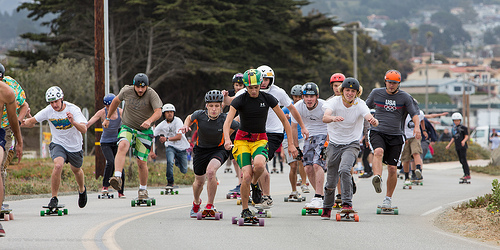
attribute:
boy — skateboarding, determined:
[235, 75, 265, 222]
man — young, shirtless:
[330, 82, 365, 207]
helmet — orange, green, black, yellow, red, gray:
[384, 69, 402, 82]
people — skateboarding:
[54, 75, 398, 206]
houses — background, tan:
[404, 50, 470, 100]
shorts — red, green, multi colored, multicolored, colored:
[109, 125, 153, 152]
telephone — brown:
[462, 101, 470, 113]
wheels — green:
[198, 212, 222, 222]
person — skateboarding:
[112, 70, 152, 209]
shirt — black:
[332, 105, 353, 140]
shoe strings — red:
[194, 213, 200, 214]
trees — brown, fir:
[123, 9, 218, 81]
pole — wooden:
[85, 23, 116, 65]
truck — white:
[465, 129, 489, 148]